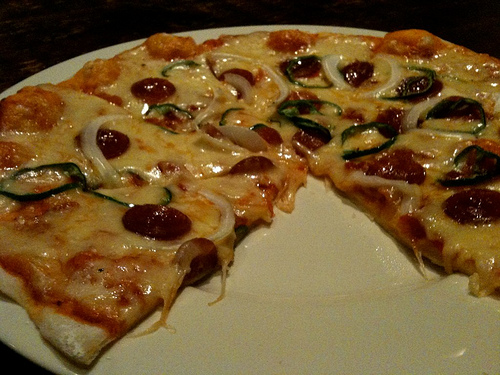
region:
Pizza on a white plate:
[1, 22, 498, 372]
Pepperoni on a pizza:
[113, 195, 197, 246]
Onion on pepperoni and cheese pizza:
[78, 104, 136, 191]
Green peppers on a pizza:
[6, 160, 173, 209]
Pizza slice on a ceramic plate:
[1, 167, 296, 367]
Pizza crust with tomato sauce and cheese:
[1, 266, 126, 369]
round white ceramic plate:
[11, 21, 489, 367]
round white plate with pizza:
[14, 18, 498, 365]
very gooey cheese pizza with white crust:
[6, 18, 499, 362]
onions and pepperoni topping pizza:
[22, 36, 492, 281]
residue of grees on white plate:
[148, 170, 479, 361]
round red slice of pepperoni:
[120, 188, 186, 248]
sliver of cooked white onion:
[85, 101, 135, 187]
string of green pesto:
[6, 151, 118, 223]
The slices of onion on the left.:
[72, 99, 230, 237]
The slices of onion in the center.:
[202, 34, 416, 164]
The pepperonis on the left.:
[75, 127, 192, 251]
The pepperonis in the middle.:
[136, 64, 351, 145]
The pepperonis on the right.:
[377, 91, 498, 222]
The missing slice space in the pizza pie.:
[103, 174, 468, 374]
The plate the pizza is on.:
[3, 27, 498, 374]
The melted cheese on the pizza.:
[7, 20, 498, 372]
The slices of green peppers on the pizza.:
[15, 88, 407, 203]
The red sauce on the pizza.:
[7, 47, 498, 319]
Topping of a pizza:
[116, 194, 189, 241]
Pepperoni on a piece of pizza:
[118, 197, 196, 243]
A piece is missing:
[149, 158, 466, 364]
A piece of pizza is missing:
[151, 186, 483, 348]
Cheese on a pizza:
[46, 204, 98, 281]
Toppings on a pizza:
[202, 48, 352, 144]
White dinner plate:
[258, 267, 416, 353]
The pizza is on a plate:
[39, 55, 425, 350]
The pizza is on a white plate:
[48, 38, 387, 352]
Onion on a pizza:
[199, 182, 229, 229]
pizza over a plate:
[4, 18, 498, 368]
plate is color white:
[1, 5, 498, 373]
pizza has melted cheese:
[5, 2, 497, 363]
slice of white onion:
[80, 106, 122, 181]